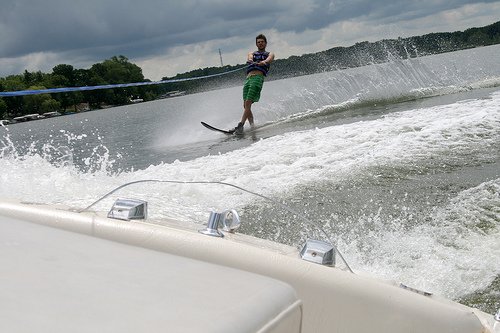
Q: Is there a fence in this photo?
A: No, there are no fences.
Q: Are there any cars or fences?
A: No, there are no fences or cars.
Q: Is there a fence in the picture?
A: No, there are no fences.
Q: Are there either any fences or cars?
A: No, there are no fences or cars.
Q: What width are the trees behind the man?
A: The trees are wide.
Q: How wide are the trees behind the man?
A: The trees are wide.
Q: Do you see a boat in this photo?
A: Yes, there is a boat.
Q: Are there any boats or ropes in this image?
A: Yes, there is a boat.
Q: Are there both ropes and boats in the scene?
A: Yes, there are both a boat and a rope.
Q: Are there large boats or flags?
A: Yes, there is a large boat.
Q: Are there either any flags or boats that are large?
A: Yes, the boat is large.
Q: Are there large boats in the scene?
A: Yes, there is a large boat.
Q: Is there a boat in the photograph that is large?
A: Yes, there is a boat that is large.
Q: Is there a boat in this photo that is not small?
A: Yes, there is a large boat.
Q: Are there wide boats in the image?
A: Yes, there is a wide boat.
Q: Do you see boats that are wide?
A: Yes, there is a boat that is wide.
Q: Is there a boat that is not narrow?
A: Yes, there is a wide boat.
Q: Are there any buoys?
A: No, there are no buoys.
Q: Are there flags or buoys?
A: No, there are no buoys or flags.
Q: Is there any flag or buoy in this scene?
A: No, there are no buoys or flags.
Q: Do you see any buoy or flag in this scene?
A: No, there are no buoys or flags.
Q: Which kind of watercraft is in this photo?
A: The watercraft is a boat.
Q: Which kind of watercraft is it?
A: The watercraft is a boat.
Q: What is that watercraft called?
A: This is a boat.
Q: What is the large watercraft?
A: The watercraft is a boat.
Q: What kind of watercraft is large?
A: The watercraft is a boat.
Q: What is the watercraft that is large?
A: The watercraft is a boat.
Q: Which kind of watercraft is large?
A: The watercraft is a boat.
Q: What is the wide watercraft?
A: The watercraft is a boat.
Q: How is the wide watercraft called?
A: The watercraft is a boat.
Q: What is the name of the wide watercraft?
A: The watercraft is a boat.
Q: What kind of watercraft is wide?
A: The watercraft is a boat.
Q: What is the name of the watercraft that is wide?
A: The watercraft is a boat.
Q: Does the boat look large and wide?
A: Yes, the boat is large and wide.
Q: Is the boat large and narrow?
A: No, the boat is large but wide.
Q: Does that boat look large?
A: Yes, the boat is large.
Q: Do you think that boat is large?
A: Yes, the boat is large.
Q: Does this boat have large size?
A: Yes, the boat is large.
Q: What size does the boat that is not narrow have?
A: The boat has large size.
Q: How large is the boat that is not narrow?
A: The boat is large.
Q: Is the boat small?
A: No, the boat is large.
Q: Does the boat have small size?
A: No, the boat is large.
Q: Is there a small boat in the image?
A: No, there is a boat but it is large.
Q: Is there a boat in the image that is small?
A: No, there is a boat but it is large.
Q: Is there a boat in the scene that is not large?
A: No, there is a boat but it is large.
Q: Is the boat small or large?
A: The boat is large.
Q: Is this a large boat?
A: Yes, this is a large boat.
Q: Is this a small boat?
A: No, this is a large boat.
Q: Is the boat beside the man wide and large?
A: Yes, the boat is wide and large.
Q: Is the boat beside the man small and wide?
A: No, the boat is wide but large.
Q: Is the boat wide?
A: Yes, the boat is wide.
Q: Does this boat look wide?
A: Yes, the boat is wide.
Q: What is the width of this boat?
A: The boat is wide.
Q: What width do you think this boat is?
A: The boat is wide.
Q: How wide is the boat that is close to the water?
A: The boat is wide.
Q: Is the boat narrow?
A: No, the boat is wide.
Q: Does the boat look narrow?
A: No, the boat is wide.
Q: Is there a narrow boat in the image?
A: No, there is a boat but it is wide.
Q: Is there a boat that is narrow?
A: No, there is a boat but it is wide.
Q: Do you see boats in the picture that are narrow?
A: No, there is a boat but it is wide.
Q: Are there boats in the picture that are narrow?
A: No, there is a boat but it is wide.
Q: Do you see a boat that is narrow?
A: No, there is a boat but it is wide.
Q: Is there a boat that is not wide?
A: No, there is a boat but it is wide.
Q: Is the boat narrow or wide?
A: The boat is wide.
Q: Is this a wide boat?
A: Yes, this is a wide boat.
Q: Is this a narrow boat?
A: No, this is a wide boat.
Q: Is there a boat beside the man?
A: Yes, there is a boat beside the man.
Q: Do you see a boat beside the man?
A: Yes, there is a boat beside the man.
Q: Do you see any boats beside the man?
A: Yes, there is a boat beside the man.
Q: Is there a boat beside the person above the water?
A: Yes, there is a boat beside the man.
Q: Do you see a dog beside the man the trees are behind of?
A: No, there is a boat beside the man.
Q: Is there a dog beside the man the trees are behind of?
A: No, there is a boat beside the man.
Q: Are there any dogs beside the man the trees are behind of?
A: No, there is a boat beside the man.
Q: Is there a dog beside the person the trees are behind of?
A: No, there is a boat beside the man.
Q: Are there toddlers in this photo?
A: No, there are no toddlers.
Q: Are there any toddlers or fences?
A: No, there are no toddlers or fences.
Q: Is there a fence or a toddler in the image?
A: No, there are no toddlers or fences.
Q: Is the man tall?
A: Yes, the man is tall.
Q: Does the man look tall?
A: Yes, the man is tall.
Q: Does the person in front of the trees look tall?
A: Yes, the man is tall.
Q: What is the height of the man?
A: The man is tall.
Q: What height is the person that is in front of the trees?
A: The man is tall.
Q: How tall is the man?
A: The man is tall.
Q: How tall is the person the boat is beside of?
A: The man is tall.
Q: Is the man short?
A: No, the man is tall.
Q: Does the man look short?
A: No, the man is tall.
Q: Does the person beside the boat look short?
A: No, the man is tall.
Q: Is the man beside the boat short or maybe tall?
A: The man is tall.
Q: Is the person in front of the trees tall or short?
A: The man is tall.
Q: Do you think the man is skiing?
A: Yes, the man is skiing.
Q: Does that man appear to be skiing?
A: Yes, the man is skiing.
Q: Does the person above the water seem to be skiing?
A: Yes, the man is skiing.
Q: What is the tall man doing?
A: The man is skiing.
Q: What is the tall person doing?
A: The man is skiing.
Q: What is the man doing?
A: The man is skiing.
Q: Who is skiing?
A: The man is skiing.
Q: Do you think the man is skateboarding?
A: No, the man is skiing.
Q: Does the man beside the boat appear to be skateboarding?
A: No, the man is skiing.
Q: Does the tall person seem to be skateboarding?
A: No, the man is skiing.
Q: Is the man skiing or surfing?
A: The man is skiing.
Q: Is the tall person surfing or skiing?
A: The man is skiing.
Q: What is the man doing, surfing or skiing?
A: The man is skiing.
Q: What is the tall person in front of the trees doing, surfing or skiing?
A: The man is skiing.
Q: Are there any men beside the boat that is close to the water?
A: Yes, there is a man beside the boat.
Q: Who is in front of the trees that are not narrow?
A: The man is in front of the trees.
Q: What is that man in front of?
A: The man is in front of the trees.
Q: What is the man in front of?
A: The man is in front of the trees.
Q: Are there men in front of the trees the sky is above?
A: Yes, there is a man in front of the trees.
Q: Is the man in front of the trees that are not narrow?
A: Yes, the man is in front of the trees.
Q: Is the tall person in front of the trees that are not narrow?
A: Yes, the man is in front of the trees.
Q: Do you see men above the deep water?
A: Yes, there is a man above the water.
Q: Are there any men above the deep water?
A: Yes, there is a man above the water.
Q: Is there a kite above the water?
A: No, there is a man above the water.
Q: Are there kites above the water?
A: No, there is a man above the water.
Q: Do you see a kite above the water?
A: No, there is a man above the water.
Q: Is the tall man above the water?
A: Yes, the man is above the water.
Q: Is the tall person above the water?
A: Yes, the man is above the water.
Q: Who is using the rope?
A: The man is using the rope.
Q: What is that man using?
A: The man is using a rope.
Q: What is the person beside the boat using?
A: The man is using a rope.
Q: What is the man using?
A: The man is using a rope.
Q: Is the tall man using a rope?
A: Yes, the man is using a rope.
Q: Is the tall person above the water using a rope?
A: Yes, the man is using a rope.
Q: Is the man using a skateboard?
A: No, the man is using a rope.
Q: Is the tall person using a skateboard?
A: No, the man is using a rope.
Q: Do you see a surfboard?
A: No, there are no surfboards.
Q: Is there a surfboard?
A: No, there are no surfboards.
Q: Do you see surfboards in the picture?
A: No, there are no surfboards.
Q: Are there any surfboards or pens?
A: No, there are no surfboards or pens.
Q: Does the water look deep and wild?
A: Yes, the water is deep and wild.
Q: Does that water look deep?
A: Yes, the water is deep.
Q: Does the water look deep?
A: Yes, the water is deep.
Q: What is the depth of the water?
A: The water is deep.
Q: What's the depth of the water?
A: The water is deep.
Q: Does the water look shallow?
A: No, the water is deep.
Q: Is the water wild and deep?
A: Yes, the water is wild and deep.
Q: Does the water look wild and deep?
A: Yes, the water is wild and deep.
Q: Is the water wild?
A: Yes, the water is wild.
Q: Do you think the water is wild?
A: Yes, the water is wild.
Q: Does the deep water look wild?
A: Yes, the water is wild.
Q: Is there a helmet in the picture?
A: No, there are no helmets.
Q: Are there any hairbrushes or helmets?
A: No, there are no helmets or hairbrushes.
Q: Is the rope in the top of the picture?
A: Yes, the rope is in the top of the image.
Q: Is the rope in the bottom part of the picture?
A: No, the rope is in the top of the image.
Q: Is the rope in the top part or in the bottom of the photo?
A: The rope is in the top of the image.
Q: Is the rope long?
A: Yes, the rope is long.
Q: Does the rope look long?
A: Yes, the rope is long.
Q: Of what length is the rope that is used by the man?
A: The rope is long.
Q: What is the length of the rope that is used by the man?
A: The rope is long.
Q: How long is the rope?
A: The rope is long.